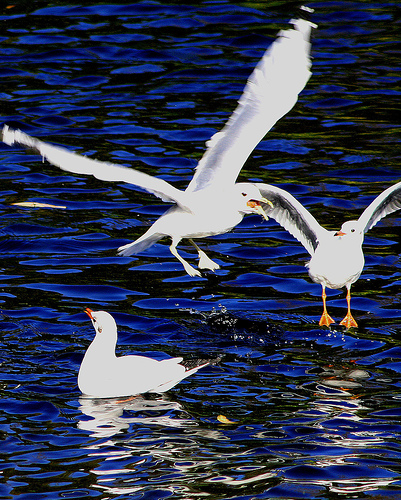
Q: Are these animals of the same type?
A: No, they are seagulls and birds.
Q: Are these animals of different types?
A: Yes, they are sea gulls and birds.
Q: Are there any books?
A: No, there are no books.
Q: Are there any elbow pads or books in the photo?
A: No, there are no books or elbow pads.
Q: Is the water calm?
A: Yes, the water is calm.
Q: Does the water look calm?
A: Yes, the water is calm.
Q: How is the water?
A: The water is calm.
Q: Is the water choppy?
A: No, the water is calm.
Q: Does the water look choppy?
A: No, the water is calm.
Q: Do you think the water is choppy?
A: No, the water is calm.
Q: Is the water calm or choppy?
A: The water is calm.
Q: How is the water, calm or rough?
A: The water is calm.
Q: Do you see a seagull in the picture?
A: Yes, there is a seagull.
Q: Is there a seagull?
A: Yes, there is a seagull.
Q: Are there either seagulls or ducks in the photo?
A: Yes, there is a seagull.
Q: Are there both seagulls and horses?
A: No, there is a seagull but no horses.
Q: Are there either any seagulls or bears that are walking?
A: Yes, the seagull is walking.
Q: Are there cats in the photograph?
A: No, there are no cats.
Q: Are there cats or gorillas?
A: No, there are no cats or gorillas.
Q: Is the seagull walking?
A: Yes, the seagull is walking.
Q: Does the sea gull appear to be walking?
A: Yes, the sea gull is walking.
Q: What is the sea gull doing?
A: The sea gull is walking.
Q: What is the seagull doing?
A: The sea gull is walking.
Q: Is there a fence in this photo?
A: No, there are no fences.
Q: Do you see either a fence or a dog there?
A: No, there are no fences or dogs.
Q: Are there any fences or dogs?
A: No, there are no fences or dogs.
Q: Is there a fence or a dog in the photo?
A: No, there are no fences or dogs.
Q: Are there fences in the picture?
A: No, there are no fences.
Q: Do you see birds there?
A: Yes, there is a bird.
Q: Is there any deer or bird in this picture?
A: Yes, there is a bird.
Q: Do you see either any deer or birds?
A: Yes, there is a bird.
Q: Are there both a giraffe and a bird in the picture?
A: No, there is a bird but no giraffes.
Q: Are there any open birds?
A: Yes, there is an open bird.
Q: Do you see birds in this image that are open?
A: Yes, there is a bird that is open.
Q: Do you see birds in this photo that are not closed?
A: Yes, there is a open bird.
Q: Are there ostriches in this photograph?
A: No, there are no ostriches.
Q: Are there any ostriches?
A: No, there are no ostriches.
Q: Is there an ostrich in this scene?
A: No, there are no ostriches.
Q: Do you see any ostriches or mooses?
A: No, there are no ostriches or mooses.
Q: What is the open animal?
A: The animal is a bird.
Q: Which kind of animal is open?
A: The animal is a bird.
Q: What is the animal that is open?
A: The animal is a bird.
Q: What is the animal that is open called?
A: The animal is a bird.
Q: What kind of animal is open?
A: The animal is a bird.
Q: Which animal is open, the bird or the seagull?
A: The bird is open.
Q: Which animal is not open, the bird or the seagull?
A: The seagull is not open.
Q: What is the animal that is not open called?
A: The animal is a seagull.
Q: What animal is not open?
A: The animal is a seagull.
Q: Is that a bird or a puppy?
A: That is a bird.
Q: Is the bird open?
A: Yes, the bird is open.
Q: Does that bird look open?
A: Yes, the bird is open.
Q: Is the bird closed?
A: No, the bird is open.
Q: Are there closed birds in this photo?
A: No, there is a bird but it is open.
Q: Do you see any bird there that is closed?
A: No, there is a bird but it is open.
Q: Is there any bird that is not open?
A: No, there is a bird but it is open.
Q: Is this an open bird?
A: Yes, this is an open bird.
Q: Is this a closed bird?
A: No, this is an open bird.